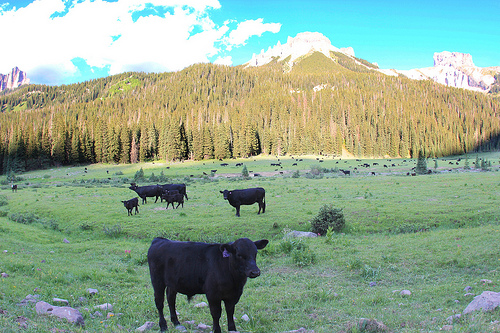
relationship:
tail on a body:
[262, 191, 267, 210] [220, 187, 267, 217]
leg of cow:
[166, 294, 193, 330] [86, 215, 316, 307]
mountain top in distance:
[0, 28, 499, 168] [0, 24, 500, 96]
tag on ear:
[222, 250, 229, 260] [220, 245, 236, 261]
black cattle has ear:
[148, 237, 270, 333] [220, 245, 236, 261]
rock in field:
[449, 286, 499, 323] [289, 166, 497, 263]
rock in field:
[449, 290, 500, 323] [3, 159, 499, 331]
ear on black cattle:
[218, 244, 230, 258] [148, 237, 270, 333]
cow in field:
[85, 201, 303, 331] [3, 159, 499, 331]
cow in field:
[118, 192, 144, 222] [16, 154, 483, 301]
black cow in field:
[155, 189, 190, 210] [3, 159, 499, 331]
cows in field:
[1, 155, 499, 330] [3, 159, 499, 331]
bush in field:
[308, 207, 351, 257] [3, 159, 499, 331]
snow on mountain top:
[264, 26, 406, 71] [2, 25, 498, 168]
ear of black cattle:
[218, 237, 235, 257] [148, 237, 270, 333]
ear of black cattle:
[255, 233, 272, 248] [148, 237, 270, 333]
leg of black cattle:
[208, 294, 223, 331] [148, 237, 270, 333]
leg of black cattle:
[225, 300, 237, 332] [148, 237, 270, 333]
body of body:
[233, 187, 263, 204] [220, 187, 267, 217]